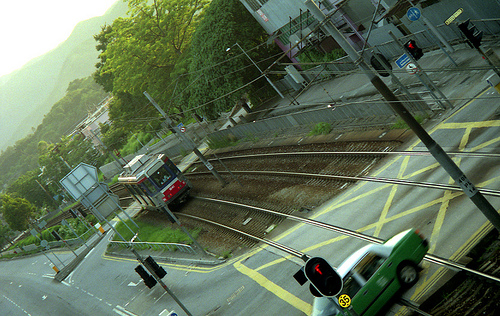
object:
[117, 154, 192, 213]
train car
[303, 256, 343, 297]
stop sign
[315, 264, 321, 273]
red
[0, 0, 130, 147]
mountain range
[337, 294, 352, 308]
sign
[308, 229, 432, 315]
taxi cab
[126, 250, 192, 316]
sign post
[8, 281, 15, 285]
arrows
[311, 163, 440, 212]
lines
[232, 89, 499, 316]
walkway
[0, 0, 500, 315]
background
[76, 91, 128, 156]
building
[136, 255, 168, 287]
sign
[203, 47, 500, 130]
street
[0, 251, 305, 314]
street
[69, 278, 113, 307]
dotted lines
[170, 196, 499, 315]
tracks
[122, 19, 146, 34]
leaves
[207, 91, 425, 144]
fence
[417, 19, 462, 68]
pole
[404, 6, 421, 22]
sign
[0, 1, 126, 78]
sky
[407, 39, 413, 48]
light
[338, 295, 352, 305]
number 35